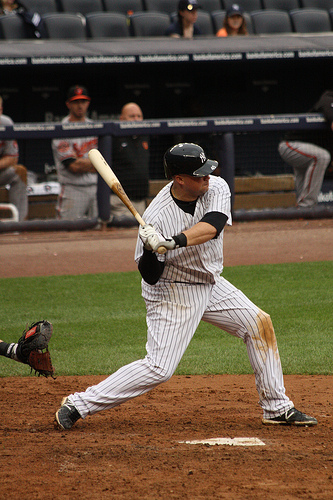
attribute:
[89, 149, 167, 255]
baseball bat — wooden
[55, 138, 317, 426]
man — holding, wearing baseball uniform, wearing a black and white stripe uniform, stripe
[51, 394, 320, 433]
sneakers — batter's, black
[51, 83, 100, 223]
man — crossing his arms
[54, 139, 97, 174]
arms — crossed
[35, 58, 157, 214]
people — in dugout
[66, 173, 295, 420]
uniform — black, white,  white, pinstriped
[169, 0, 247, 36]
spectators — watching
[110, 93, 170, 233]
man — wearing black shirt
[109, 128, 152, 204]
shirt — black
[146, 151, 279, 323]
man — wearing baseball helmet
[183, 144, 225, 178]
helmet — baseball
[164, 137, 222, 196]
head — man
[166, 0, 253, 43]
spectators — in bleachers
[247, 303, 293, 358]
dirt — on man's pants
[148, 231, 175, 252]
glove —  white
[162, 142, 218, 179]
helmet — dark, baseball, batting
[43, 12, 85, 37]
chair — empty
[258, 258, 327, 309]
grass — patch, green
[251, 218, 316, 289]
ground — brown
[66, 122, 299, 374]
man — wearing a black hard hat, hard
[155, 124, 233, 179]
hat — black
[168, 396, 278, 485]
plate — home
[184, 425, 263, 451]
home plate — white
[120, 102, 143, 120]
head — bald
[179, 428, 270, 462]
plate — home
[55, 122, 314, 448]
baseball player — wearing white and black pinstriped uniform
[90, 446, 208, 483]
dirt — brown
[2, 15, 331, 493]
game — baseball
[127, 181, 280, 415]
uniform — baseball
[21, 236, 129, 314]
field — baseball